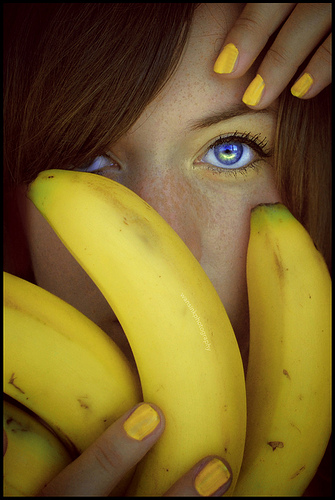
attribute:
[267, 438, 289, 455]
spot — small, brown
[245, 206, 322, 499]
banana — yellow, bruise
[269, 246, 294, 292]
line — small, green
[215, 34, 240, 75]
girl — fair skin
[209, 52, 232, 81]
fingernail — yellow, painted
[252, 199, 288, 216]
tip — green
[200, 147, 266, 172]
eye — shining, blue, yellow, white, reflecting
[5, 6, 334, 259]
hair — auborn, red, auburn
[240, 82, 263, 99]
polish — yellow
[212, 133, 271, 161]
eyelash — coated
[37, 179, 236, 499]
banana — yellow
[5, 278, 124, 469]
banana — yellow